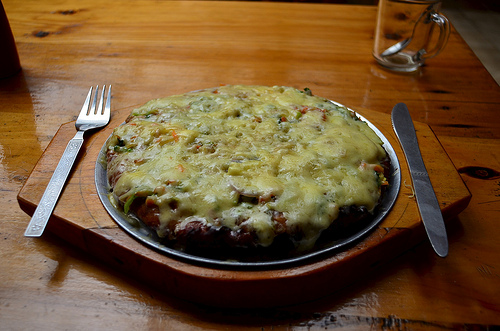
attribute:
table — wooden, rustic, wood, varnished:
[0, 2, 499, 330]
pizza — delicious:
[103, 84, 393, 255]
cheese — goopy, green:
[103, 85, 392, 261]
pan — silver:
[94, 98, 402, 273]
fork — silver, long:
[24, 83, 111, 238]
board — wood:
[17, 97, 469, 301]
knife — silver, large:
[391, 101, 449, 255]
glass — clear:
[373, 1, 447, 72]